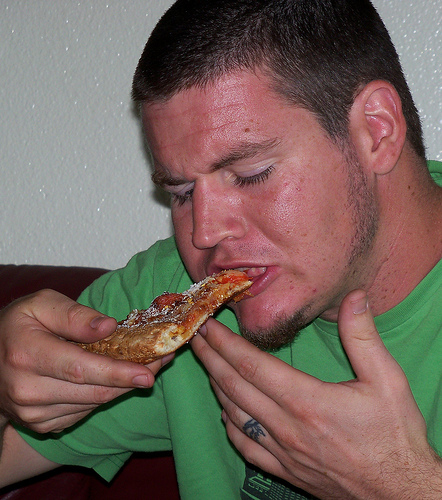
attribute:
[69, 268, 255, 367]
pizza — slice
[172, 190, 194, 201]
eyelashes — feminine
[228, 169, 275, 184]
eyelashes — feminine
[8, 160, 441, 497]
shirt — green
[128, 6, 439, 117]
hair — short, brown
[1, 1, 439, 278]
wall — white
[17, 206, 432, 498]
shirt — green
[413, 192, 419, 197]
freckle — small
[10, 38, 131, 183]
wall — white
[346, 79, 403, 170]
ear — human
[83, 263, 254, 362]
pizza — peice, cheesy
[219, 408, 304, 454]
tattoo — black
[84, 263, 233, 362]
pizza — slice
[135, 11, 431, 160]
hair — brown, short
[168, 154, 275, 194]
eyes — closed